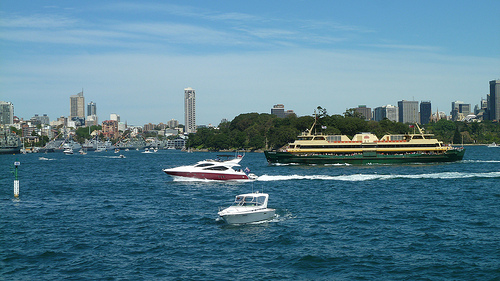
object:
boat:
[217, 182, 275, 224]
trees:
[186, 94, 500, 152]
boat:
[163, 149, 250, 180]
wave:
[172, 172, 500, 182]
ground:
[391, 110, 404, 122]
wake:
[258, 171, 500, 182]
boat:
[263, 121, 466, 164]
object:
[14, 162, 21, 200]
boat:
[118, 154, 125, 158]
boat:
[39, 150, 57, 160]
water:
[0, 144, 500, 281]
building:
[397, 99, 420, 125]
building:
[0, 101, 14, 125]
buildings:
[344, 80, 499, 124]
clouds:
[1, 0, 498, 127]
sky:
[1, 0, 499, 128]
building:
[184, 87, 195, 133]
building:
[69, 87, 84, 117]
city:
[0, 80, 500, 154]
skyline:
[1, 84, 483, 127]